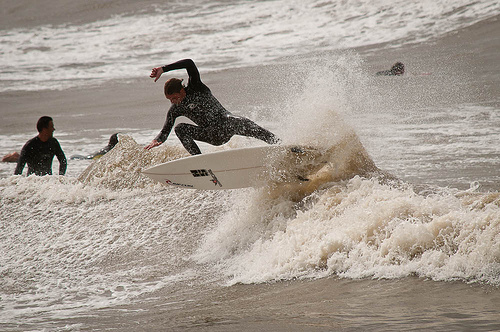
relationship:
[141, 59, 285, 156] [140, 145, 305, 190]
surfer rides surfboard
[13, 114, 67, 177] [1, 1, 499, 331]
surfer in water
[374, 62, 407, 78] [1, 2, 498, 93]
swimmer swimming in water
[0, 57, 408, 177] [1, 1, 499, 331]
group in water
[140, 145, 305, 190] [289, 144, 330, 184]
surfboard has tail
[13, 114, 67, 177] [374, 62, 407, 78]
man watches swimmer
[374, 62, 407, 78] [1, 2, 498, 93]
swimmer in water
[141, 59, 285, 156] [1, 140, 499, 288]
surfer rides wave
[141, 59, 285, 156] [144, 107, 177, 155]
surfer extends arm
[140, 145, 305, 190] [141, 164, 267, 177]
surfboard has line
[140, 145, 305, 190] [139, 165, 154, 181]
surfboard has nose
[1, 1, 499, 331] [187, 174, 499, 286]
water has foam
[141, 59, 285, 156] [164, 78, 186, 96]
surfer has hair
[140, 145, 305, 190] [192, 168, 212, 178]
surfboard has logo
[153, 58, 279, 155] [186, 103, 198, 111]
wetsuit has decal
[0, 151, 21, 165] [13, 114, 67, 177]
rock behind surfer